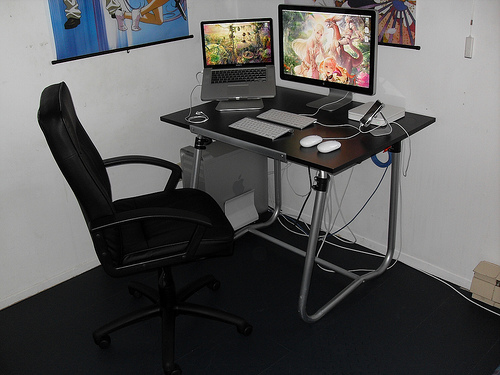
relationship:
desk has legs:
[159, 81, 436, 323] [190, 133, 400, 322]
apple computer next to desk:
[180, 140, 268, 230] [159, 81, 436, 323]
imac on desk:
[277, 2, 378, 111] [159, 81, 436, 323]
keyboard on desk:
[228, 115, 295, 140] [159, 81, 436, 323]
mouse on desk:
[316, 139, 342, 154] [159, 81, 436, 323]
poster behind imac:
[286, 0, 421, 50] [277, 2, 378, 111]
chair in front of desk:
[37, 81, 253, 373] [159, 81, 436, 323]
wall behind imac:
[237, 1, 500, 289] [277, 2, 378, 111]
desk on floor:
[159, 81, 436, 323] [0, 209, 500, 374]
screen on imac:
[280, 8, 371, 89] [277, 2, 378, 111]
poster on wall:
[43, 0, 194, 66] [0, 0, 240, 311]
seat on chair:
[110, 186, 233, 265] [37, 81, 253, 373]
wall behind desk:
[237, 1, 500, 289] [159, 81, 436, 323]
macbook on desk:
[200, 17, 276, 103] [159, 81, 436, 323]